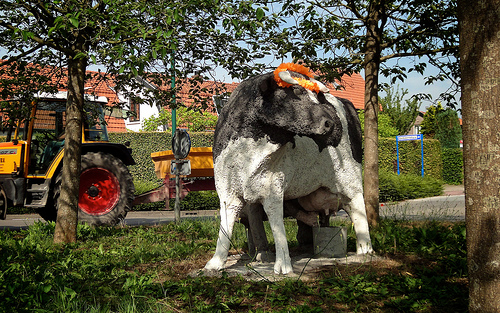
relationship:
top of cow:
[271, 64, 341, 113] [178, 56, 376, 251]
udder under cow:
[317, 195, 365, 248] [178, 56, 376, 251]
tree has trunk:
[68, 26, 171, 85] [44, 95, 106, 255]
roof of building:
[125, 85, 172, 120] [91, 94, 216, 184]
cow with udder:
[178, 56, 376, 251] [317, 195, 365, 248]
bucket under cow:
[313, 208, 347, 242] [178, 56, 376, 251]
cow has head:
[178, 56, 376, 251] [234, 58, 342, 156]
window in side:
[92, 87, 155, 140] [81, 79, 206, 141]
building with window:
[91, 94, 216, 184] [92, 87, 155, 140]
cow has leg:
[178, 56, 376, 251] [250, 197, 299, 269]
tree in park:
[68, 26, 171, 85] [13, 164, 191, 312]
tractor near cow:
[2, 74, 139, 233] [178, 56, 376, 251]